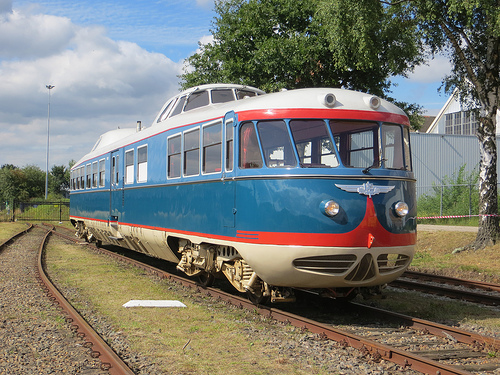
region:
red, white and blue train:
[77, 86, 418, 305]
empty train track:
[1, 222, 136, 370]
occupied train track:
[262, 266, 498, 372]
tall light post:
[42, 79, 57, 204]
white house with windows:
[429, 73, 483, 133]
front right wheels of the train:
[168, 231, 278, 304]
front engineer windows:
[231, 113, 413, 174]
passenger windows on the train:
[164, 127, 229, 178]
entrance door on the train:
[107, 147, 120, 229]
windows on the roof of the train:
[148, 86, 269, 129]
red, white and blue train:
[65, 80, 422, 302]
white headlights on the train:
[316, 197, 411, 222]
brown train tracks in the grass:
[1, 221, 498, 373]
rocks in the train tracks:
[0, 226, 109, 373]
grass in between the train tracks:
[45, 227, 332, 373]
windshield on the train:
[236, 115, 413, 175]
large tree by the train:
[209, 1, 496, 253]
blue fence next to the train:
[336, 123, 498, 206]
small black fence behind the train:
[0, 193, 73, 225]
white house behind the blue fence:
[419, 69, 497, 149]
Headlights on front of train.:
[312, 194, 414, 223]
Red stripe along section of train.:
[134, 212, 271, 249]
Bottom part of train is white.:
[92, 210, 328, 317]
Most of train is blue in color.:
[69, 153, 321, 215]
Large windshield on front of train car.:
[259, 127, 424, 164]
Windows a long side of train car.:
[56, 158, 234, 190]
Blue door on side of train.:
[99, 152, 129, 230]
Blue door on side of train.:
[213, 120, 246, 244]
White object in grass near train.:
[122, 288, 212, 338]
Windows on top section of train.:
[178, 83, 250, 113]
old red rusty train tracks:
[2, 218, 498, 373]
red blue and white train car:
[66, 82, 421, 311]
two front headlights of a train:
[321, 198, 411, 220]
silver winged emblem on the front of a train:
[332, 180, 397, 199]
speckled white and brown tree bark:
[437, 2, 499, 252]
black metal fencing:
[2, 194, 72, 224]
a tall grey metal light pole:
[42, 82, 54, 204]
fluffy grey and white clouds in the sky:
[0, 2, 222, 176]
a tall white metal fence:
[409, 132, 481, 224]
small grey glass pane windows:
[442, 106, 483, 136]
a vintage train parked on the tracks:
[68, 81, 416, 302]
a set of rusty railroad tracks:
[0, 219, 499, 374]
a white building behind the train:
[408, 74, 498, 139]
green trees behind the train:
[176, 0, 499, 255]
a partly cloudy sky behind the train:
[0, 0, 499, 175]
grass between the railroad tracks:
[45, 238, 332, 373]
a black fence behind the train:
[0, 198, 70, 220]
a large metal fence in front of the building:
[338, 128, 498, 211]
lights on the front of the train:
[323, 200, 408, 220]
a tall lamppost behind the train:
[45, 83, 53, 199]